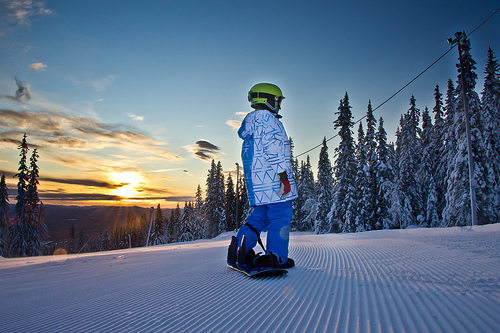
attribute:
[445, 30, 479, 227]
light post — tall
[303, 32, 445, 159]
cable — large, hanging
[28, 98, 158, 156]
clouds — white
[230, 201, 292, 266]
pants — blue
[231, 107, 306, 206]
jacket — large, white, blue